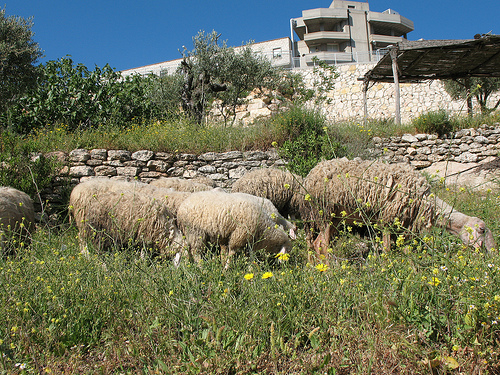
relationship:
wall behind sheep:
[2, 123, 499, 222] [176, 189, 300, 272]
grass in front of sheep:
[4, 231, 499, 373] [176, 189, 300, 272]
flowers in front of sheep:
[260, 273, 274, 281] [176, 189, 300, 272]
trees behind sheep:
[182, 28, 270, 129] [176, 189, 300, 272]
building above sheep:
[86, 1, 415, 84] [176, 189, 300, 272]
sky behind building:
[3, 2, 498, 78] [86, 1, 415, 84]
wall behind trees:
[207, 62, 497, 130] [182, 28, 270, 129]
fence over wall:
[273, 52, 386, 64] [207, 62, 497, 130]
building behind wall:
[86, 1, 415, 84] [207, 62, 497, 130]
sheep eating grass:
[176, 189, 300, 272] [4, 231, 499, 373]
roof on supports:
[362, 35, 498, 85] [389, 46, 402, 131]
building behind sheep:
[86, 1, 415, 84] [176, 189, 300, 272]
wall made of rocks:
[2, 123, 499, 222] [133, 149, 154, 163]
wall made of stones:
[2, 123, 499, 222] [133, 149, 154, 163]